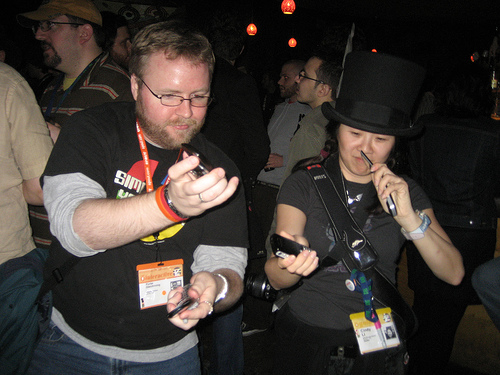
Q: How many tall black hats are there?
A: 1.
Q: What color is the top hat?
A: Black.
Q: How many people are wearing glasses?
A: 3.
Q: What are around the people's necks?
A: Identification badges.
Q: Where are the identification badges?
A: Around the people's necks.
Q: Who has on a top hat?
A: Person on the right.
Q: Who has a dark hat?
A: The woman.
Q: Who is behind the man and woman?
A: People in the background.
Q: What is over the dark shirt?
A: Cross body strap.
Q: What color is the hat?
A: Black.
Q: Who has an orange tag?
A: The man.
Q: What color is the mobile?
A: Black.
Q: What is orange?
A: The hanging lights.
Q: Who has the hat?
A: The woman.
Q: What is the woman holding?
A: Mobile.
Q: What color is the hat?
A: Black.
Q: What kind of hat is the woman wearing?
A: A top hat.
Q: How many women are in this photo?
A: One.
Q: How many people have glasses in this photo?
A: Three.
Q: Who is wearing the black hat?
A: The girl.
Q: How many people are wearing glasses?
A: Three.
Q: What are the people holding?
A: Phones.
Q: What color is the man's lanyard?
A: Orange.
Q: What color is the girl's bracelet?
A: Blue.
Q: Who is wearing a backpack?
A: The girl.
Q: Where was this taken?
A: At a convention.